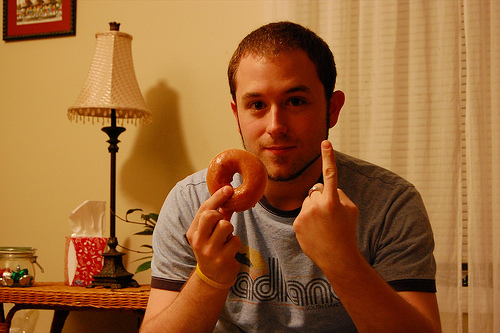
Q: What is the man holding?
A: A donut.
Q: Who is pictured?
A: A man.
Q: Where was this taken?
A: A living room.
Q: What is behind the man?
A: A window.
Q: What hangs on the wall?
A: A picture.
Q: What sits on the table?
A: A lamp.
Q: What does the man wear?
A: A gray t-shirt.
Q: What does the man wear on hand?
A: A ring.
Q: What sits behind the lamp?
A: A box of tissues.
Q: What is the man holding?
A: Donut.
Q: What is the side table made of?
A: Wicker.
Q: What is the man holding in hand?
A: Donuts.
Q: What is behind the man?
A: Curtain.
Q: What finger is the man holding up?
A: Index finger.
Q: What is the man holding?
A: A donut.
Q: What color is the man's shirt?
A: Grey.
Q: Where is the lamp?
A: On a table.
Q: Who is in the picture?
A: A man.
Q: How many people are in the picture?
A: One.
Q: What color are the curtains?
A: White.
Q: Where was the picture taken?
A: In a living room.